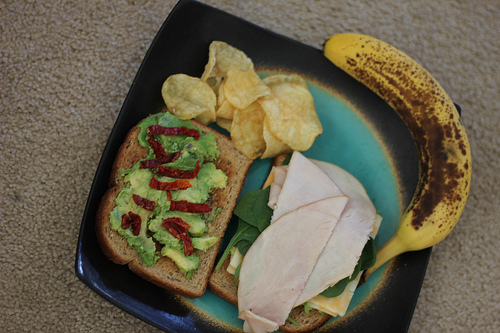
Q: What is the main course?
A: Sandwich.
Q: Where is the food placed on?
A: Plate.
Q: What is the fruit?
A: Banana.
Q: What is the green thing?
A: Avocado.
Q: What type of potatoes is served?
A: Potato chips.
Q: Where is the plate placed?
A: On carpet.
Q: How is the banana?
A: Ripe.